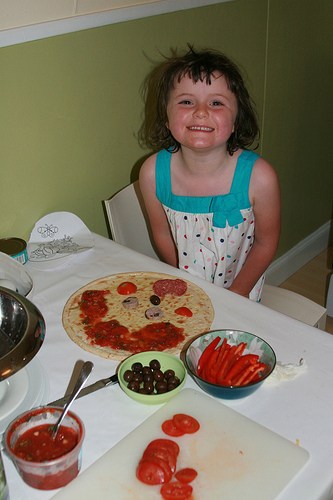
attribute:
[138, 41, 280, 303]
girl — smiling, sitting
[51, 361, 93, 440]
spoon — metal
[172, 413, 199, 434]
tomato — sliced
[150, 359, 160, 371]
olive — black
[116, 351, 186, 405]
bowl — green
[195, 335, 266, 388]
bell peppers — sliced, red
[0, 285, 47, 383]
colander — silver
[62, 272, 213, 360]
pizza — unfinished, whole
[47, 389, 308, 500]
cutting board — white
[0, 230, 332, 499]
table — white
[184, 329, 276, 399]
bowl — blue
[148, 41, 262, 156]
hair — short